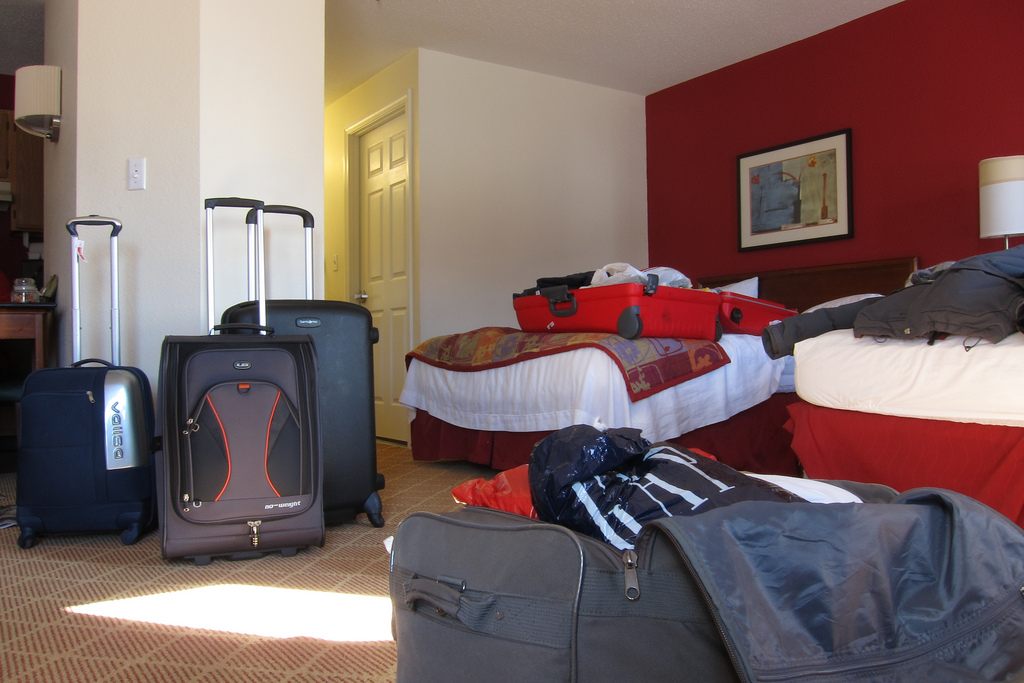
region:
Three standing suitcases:
[12, 195, 386, 560]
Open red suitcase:
[508, 263, 803, 346]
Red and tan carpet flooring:
[0, 434, 533, 678]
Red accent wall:
[642, 0, 1022, 292]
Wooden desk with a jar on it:
[0, 271, 64, 529]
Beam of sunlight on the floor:
[54, 577, 400, 648]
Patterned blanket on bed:
[400, 254, 925, 479]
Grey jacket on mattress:
[758, 241, 1022, 431]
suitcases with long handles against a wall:
[25, 191, 381, 566]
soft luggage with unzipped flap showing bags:
[376, 415, 1019, 673]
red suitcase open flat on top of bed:
[398, 263, 797, 475]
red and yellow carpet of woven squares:
[9, 453, 475, 670]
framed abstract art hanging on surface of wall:
[641, 4, 984, 280]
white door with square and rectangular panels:
[341, 83, 424, 447]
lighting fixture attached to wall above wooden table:
[9, 22, 71, 367]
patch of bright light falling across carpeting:
[26, 553, 393, 662]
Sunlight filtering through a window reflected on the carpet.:
[62, 575, 396, 646]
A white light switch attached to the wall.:
[122, 148, 151, 196]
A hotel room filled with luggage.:
[15, 181, 1022, 679]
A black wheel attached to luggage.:
[610, 301, 649, 340]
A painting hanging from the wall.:
[727, 133, 858, 250]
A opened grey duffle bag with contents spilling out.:
[381, 448, 1023, 680]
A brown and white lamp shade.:
[970, 149, 1022, 248]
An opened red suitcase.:
[511, 252, 800, 345]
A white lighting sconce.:
[10, 57, 65, 138]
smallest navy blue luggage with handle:
[16, 211, 162, 547]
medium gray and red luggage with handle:
[156, 197, 330, 564]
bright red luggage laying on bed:
[513, 260, 798, 343]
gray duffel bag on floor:
[387, 478, 1021, 679]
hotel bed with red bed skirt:
[396, 252, 919, 471]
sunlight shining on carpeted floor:
[57, 579, 394, 643]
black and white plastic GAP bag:
[526, 412, 814, 550]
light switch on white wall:
[124, 151, 147, 187]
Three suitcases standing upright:
[18, 189, 389, 563]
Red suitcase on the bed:
[514, 268, 787, 351]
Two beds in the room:
[404, 256, 1021, 514]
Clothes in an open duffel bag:
[385, 419, 1021, 679]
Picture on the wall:
[730, 123, 857, 259]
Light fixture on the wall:
[14, 55, 60, 139]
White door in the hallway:
[350, 105, 417, 429]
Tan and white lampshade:
[979, 144, 1021, 244]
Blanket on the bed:
[409, 310, 732, 405]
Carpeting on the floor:
[0, 434, 479, 678]